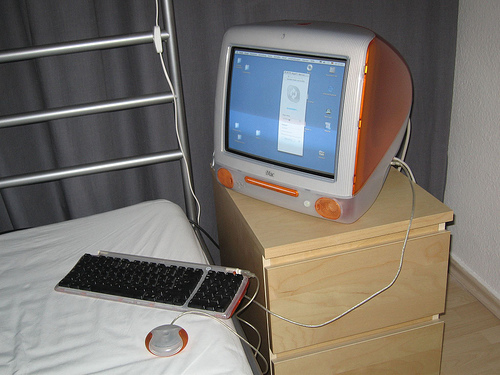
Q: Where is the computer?
A: On a table.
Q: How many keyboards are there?
A: One.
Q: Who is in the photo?
A: No one that is visible.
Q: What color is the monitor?
A: Orange.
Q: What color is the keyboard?
A: Black.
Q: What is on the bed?
A: A keyboard and mouse.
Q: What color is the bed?
A: White.